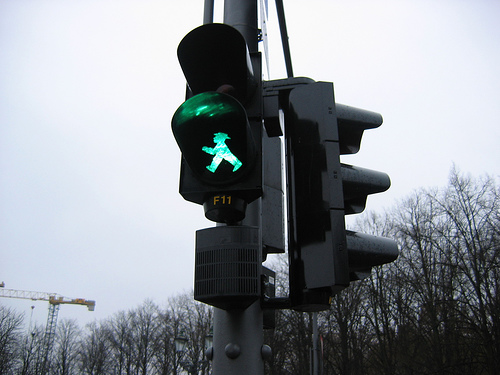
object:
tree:
[114, 304, 150, 375]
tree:
[425, 183, 460, 375]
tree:
[85, 313, 114, 375]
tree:
[31, 318, 58, 373]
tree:
[0, 308, 26, 373]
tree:
[129, 298, 164, 373]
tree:
[161, 298, 186, 375]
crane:
[0, 280, 96, 375]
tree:
[188, 294, 210, 375]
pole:
[205, 307, 272, 375]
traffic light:
[170, 23, 276, 311]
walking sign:
[170, 22, 264, 223]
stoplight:
[263, 77, 399, 312]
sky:
[1, 0, 75, 209]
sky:
[131, 0, 168, 286]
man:
[202, 131, 243, 173]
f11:
[214, 195, 232, 205]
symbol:
[202, 131, 243, 173]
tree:
[465, 176, 499, 375]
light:
[169, 22, 261, 313]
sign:
[171, 91, 256, 223]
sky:
[416, 0, 499, 176]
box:
[261, 76, 399, 329]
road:
[0, 348, 500, 375]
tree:
[325, 280, 365, 374]